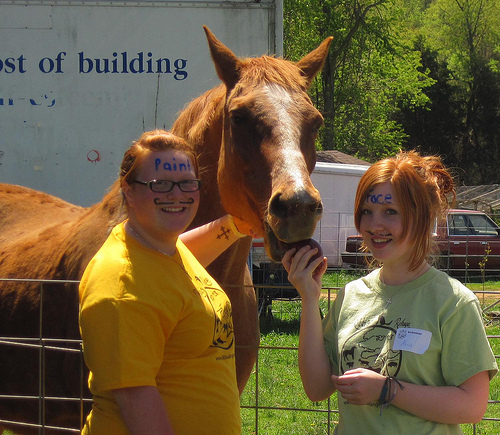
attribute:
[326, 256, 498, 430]
shirt — green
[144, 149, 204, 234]
face — painted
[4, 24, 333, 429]
horse — brown, happy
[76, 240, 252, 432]
shirt — woman's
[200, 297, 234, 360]
print — graphic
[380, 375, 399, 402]
bracelets — braided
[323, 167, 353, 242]
truck — large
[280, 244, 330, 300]
hand — GIRL'S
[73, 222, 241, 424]
shirt — YELLOW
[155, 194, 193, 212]
mustache — painted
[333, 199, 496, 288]
car — marron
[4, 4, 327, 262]
house — big, reddish brown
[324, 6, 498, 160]
trees — tall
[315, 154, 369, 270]
trailer — white